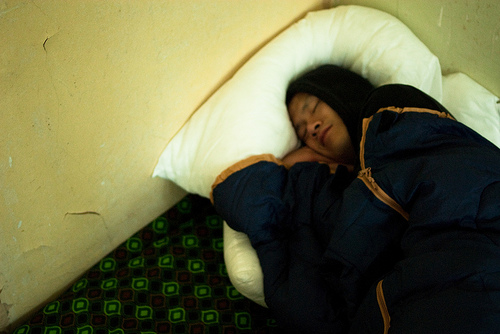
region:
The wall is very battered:
[0, 3, 112, 331]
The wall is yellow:
[1, 1, 328, 326]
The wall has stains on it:
[327, 1, 497, 98]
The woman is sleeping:
[212, 62, 498, 332]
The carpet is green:
[2, 189, 289, 331]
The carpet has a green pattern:
[0, 191, 273, 331]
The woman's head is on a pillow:
[147, 6, 437, 194]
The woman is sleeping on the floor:
[213, 66, 495, 333]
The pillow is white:
[151, 6, 443, 203]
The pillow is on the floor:
[153, 6, 440, 201]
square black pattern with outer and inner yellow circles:
[63, 293, 95, 319]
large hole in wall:
[59, 198, 119, 245]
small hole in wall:
[33, 23, 74, 74]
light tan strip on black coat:
[354, 164, 412, 219]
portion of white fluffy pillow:
[212, 221, 262, 309]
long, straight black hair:
[289, 61, 398, 106]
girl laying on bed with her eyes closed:
[283, 91, 346, 138]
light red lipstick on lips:
[315, 124, 345, 152]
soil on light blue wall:
[419, 3, 499, 65]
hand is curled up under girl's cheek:
[285, 142, 341, 177]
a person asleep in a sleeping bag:
[275, 50, 485, 327]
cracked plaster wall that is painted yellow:
[10, 5, 110, 230]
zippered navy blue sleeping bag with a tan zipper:
[210, 185, 495, 290]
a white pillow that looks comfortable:
[180, 75, 275, 140]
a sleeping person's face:
[280, 80, 350, 155]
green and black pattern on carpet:
[95, 265, 210, 330]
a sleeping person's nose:
[300, 110, 325, 135]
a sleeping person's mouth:
[320, 110, 330, 150]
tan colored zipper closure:
[355, 135, 420, 225]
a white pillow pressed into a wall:
[160, 60, 276, 142]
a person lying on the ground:
[213, 63, 498, 333]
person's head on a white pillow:
[265, 34, 377, 160]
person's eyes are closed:
[294, 93, 320, 144]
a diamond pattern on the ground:
[110, 259, 195, 331]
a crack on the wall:
[60, 200, 120, 252]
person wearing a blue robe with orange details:
[357, 95, 450, 222]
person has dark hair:
[310, 66, 358, 105]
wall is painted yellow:
[62, 83, 142, 173]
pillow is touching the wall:
[217, 0, 414, 67]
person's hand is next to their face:
[282, 119, 352, 183]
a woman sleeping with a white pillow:
[153, 36, 491, 321]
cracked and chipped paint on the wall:
[11, 182, 126, 263]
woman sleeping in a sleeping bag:
[233, 67, 496, 332]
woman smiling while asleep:
[276, 56, 403, 181]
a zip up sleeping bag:
[243, 140, 485, 332]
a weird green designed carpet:
[20, 198, 302, 332]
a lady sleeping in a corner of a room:
[219, 2, 493, 252]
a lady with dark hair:
[282, 56, 381, 161]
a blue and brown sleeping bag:
[206, 128, 498, 330]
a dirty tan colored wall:
[7, 0, 279, 305]